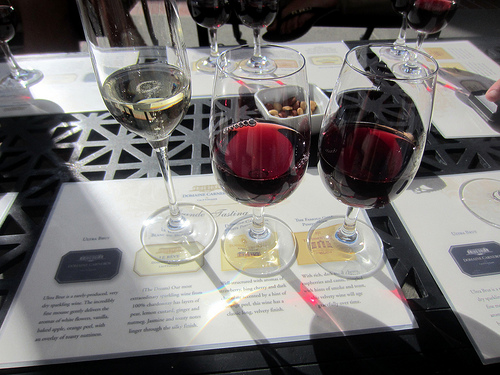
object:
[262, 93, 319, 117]
nuts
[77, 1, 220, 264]
glass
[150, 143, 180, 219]
neck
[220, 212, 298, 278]
base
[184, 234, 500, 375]
shadow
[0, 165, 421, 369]
placemat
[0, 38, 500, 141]
menus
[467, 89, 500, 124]
machine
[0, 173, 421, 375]
menu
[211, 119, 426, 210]
wine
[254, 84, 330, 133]
plate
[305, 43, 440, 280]
glass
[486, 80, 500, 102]
finger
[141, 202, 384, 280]
rim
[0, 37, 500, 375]
table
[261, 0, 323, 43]
sandal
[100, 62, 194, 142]
wine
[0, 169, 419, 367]
paper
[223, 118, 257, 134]
bubbles